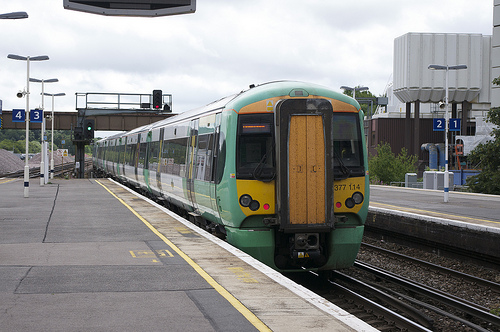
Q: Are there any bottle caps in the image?
A: No, there are no bottle caps.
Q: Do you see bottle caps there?
A: No, there are no bottle caps.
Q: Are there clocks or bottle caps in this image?
A: No, there are no bottle caps or clocks.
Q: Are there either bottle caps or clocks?
A: No, there are no bottle caps or clocks.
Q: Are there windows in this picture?
A: Yes, there is a window.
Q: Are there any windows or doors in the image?
A: Yes, there is a window.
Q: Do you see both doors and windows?
A: Yes, there are both a window and a door.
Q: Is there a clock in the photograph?
A: No, there are no clocks.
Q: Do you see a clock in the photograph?
A: No, there are no clocks.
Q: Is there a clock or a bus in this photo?
A: No, there are no clocks or buses.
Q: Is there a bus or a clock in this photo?
A: No, there are no clocks or buses.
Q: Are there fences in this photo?
A: No, there are no fences.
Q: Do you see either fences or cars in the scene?
A: No, there are no fences or cars.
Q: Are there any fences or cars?
A: No, there are no fences or cars.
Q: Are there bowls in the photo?
A: No, there are no bowls.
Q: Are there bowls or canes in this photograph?
A: No, there are no bowls or canes.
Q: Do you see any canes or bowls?
A: No, there are no bowls or canes.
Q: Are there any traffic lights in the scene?
A: Yes, there is a traffic light.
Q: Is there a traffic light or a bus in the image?
A: Yes, there is a traffic light.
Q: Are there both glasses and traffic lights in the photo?
A: No, there is a traffic light but no glasses.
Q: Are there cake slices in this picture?
A: No, there are no cake slices.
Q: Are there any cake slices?
A: No, there are no cake slices.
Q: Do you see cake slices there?
A: No, there are no cake slices.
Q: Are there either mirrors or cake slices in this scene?
A: No, there are no cake slices or mirrors.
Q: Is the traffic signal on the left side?
A: Yes, the traffic signal is on the left of the image.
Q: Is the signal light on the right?
A: No, the signal light is on the left of the image.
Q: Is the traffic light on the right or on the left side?
A: The traffic light is on the left of the image.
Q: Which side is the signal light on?
A: The signal light is on the left of the image.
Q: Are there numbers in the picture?
A: Yes, there are numbers.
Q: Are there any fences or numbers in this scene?
A: Yes, there are numbers.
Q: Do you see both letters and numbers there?
A: No, there are numbers but no letters.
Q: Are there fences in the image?
A: No, there are no fences.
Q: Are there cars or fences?
A: No, there are no fences or cars.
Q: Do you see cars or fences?
A: No, there are no fences or cars.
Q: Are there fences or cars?
A: No, there are no fences or cars.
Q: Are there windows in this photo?
A: Yes, there are windows.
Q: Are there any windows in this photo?
A: Yes, there are windows.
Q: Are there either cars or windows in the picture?
A: Yes, there are windows.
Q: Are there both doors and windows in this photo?
A: Yes, there are both windows and doors.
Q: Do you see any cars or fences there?
A: No, there are no cars or fences.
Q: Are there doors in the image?
A: Yes, there is a door.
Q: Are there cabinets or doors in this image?
A: Yes, there is a door.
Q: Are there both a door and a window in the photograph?
A: Yes, there are both a door and a window.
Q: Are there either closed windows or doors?
A: Yes, there is a closed door.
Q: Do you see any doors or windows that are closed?
A: Yes, the door is closed.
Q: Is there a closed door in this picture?
A: Yes, there is a closed door.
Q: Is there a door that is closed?
A: Yes, there is a door that is closed.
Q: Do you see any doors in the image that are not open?
A: Yes, there is an closed door.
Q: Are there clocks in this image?
A: No, there are no clocks.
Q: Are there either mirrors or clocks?
A: No, there are no clocks or mirrors.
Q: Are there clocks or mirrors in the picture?
A: No, there are no clocks or mirrors.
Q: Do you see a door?
A: Yes, there is a door.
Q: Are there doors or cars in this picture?
A: Yes, there is a door.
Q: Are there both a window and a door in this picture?
A: Yes, there are both a door and a window.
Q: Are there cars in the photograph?
A: No, there are no cars.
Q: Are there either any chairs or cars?
A: No, there are no cars or chairs.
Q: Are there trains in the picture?
A: Yes, there is a train.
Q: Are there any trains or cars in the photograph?
A: Yes, there is a train.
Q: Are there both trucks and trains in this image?
A: No, there is a train but no trucks.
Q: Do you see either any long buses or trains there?
A: Yes, there is a long train.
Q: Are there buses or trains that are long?
A: Yes, the train is long.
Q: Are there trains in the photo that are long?
A: Yes, there is a long train.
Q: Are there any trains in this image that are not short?
A: Yes, there is a long train.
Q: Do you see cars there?
A: No, there are no cars.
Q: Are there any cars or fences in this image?
A: No, there are no cars or fences.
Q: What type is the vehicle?
A: The vehicle is a train.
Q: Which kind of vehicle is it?
A: The vehicle is a train.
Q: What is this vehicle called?
A: This is a train.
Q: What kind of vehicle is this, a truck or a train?
A: This is a train.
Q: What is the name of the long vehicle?
A: The vehicle is a train.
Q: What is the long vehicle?
A: The vehicle is a train.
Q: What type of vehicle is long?
A: The vehicle is a train.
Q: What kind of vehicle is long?
A: The vehicle is a train.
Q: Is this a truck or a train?
A: This is a train.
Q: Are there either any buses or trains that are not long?
A: No, there is a train but it is long.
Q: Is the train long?
A: Yes, the train is long.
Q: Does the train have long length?
A: Yes, the train is long.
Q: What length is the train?
A: The train is long.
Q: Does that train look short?
A: No, the train is long.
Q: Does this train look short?
A: No, the train is long.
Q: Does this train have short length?
A: No, the train is long.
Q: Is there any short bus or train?
A: No, there is a train but it is long.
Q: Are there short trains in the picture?
A: No, there is a train but it is long.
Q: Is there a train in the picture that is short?
A: No, there is a train but it is long.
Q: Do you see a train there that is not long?
A: No, there is a train but it is long.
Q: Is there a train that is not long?
A: No, there is a train but it is long.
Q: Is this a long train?
A: Yes, this is a long train.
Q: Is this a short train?
A: No, this is a long train.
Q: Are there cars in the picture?
A: No, there are no cars.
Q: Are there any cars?
A: No, there are no cars.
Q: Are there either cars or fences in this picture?
A: No, there are no cars or fences.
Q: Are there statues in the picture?
A: No, there are no statues.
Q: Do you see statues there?
A: No, there are no statues.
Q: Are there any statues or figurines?
A: No, there are no statues or figurines.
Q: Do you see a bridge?
A: Yes, there is a bridge.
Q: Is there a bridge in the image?
A: Yes, there is a bridge.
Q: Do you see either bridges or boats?
A: Yes, there is a bridge.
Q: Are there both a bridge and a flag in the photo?
A: No, there is a bridge but no flags.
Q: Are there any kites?
A: No, there are no kites.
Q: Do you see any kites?
A: No, there are no kites.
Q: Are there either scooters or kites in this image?
A: No, there are no kites or scooters.